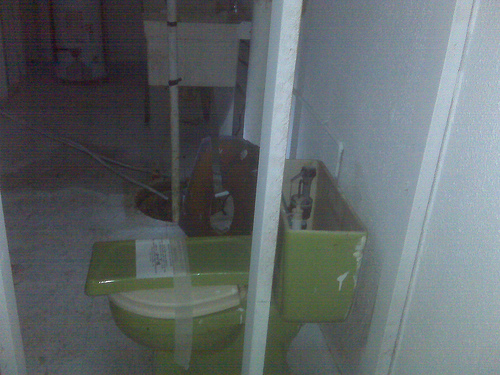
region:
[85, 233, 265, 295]
Green toilet tank atop lid.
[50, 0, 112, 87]
White hot water tank.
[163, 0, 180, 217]
White pole part of plumbing.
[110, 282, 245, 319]
Tan toilet lid closed.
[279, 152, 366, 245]
Open back tank of toilet.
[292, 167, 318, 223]
Inside plumbing of toilet.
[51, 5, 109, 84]
Hot water tank in background.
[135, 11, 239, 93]
White sink in basement.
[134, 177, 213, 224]
Open hole in bathroom floor.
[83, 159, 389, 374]
Green toilet in disrepair.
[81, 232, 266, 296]
green toilet tank cover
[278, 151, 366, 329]
green toilet tank against block wall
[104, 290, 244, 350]
green toilet bowl with ivory cover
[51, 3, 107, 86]
hot water heater n back ground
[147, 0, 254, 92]
slop sink and faucet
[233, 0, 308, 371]
white painted wood for wall framing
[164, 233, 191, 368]
tape holding tank cover to toilet bowl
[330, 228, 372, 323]
white paint on toilet tank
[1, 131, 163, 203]
water spot on floor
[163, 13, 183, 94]
black tape around PVC pipe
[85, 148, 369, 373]
A green broken toilet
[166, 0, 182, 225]
Tubing coming out of the floor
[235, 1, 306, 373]
A wooden beam in the foreground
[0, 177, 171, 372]
Carpet on the floor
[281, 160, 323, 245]
The plumbing inter-workings of the toilet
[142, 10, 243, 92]
A large industrial sink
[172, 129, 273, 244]
A ceramic blue/brown piece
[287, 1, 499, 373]
A white wall behind the toilet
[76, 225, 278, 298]
The green toilet lid strapped to the toilet bowl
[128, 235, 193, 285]
Toilet information strapped to the lid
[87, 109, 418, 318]
a toilet inside a house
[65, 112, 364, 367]
a bathroom toilet inside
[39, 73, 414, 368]
a green bathroom toilet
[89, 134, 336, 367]
a green bathroom toilet inside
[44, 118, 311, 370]
a toilet with a white seat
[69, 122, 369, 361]
a toilet with a white lid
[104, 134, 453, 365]
a green toilet with white lid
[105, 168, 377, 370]
green toilet with white seat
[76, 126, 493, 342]
a bathroom toilet that is green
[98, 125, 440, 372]
a toilet that is green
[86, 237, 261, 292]
toilet covering with sign on top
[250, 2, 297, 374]
white post in spare bathroom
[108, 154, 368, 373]
green toilet with covering removed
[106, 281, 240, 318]
beige toilet seat cover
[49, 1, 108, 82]
water heater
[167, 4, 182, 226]
white post with black electrical tape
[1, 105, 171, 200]
electrical cables leading out of hole in the bathroom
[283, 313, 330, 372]
white baseboard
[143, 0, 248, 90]
white sink at the edge of the bathroom area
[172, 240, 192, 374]
tape attaching toilet covering to seat